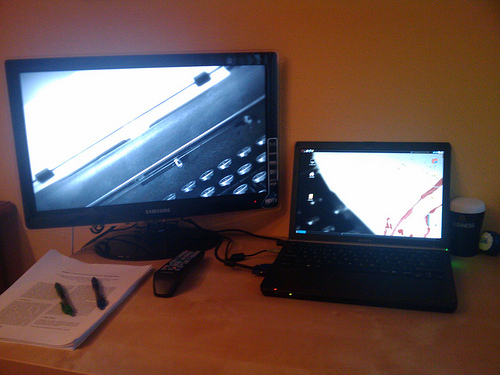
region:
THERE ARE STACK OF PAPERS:
[0, 245, 153, 356]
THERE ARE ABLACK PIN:
[51, 278, 76, 318]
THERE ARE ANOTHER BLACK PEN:
[89, 272, 109, 314]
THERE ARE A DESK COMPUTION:
[0, 49, 279, 266]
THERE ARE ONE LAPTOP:
[258, 140, 461, 315]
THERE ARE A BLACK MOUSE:
[152, 245, 215, 295]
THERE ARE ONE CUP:
[446, 195, 484, 260]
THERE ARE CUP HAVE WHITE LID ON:
[448, 195, 486, 217]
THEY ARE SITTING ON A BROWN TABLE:
[0, 45, 497, 372]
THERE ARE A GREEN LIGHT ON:
[285, 287, 296, 297]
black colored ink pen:
[87, 274, 110, 311]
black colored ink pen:
[51, 278, 78, 320]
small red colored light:
[271, 285, 278, 290]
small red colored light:
[251, 198, 256, 203]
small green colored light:
[286, 291, 296, 296]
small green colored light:
[441, 246, 448, 250]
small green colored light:
[448, 258, 463, 268]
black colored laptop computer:
[262, 138, 462, 315]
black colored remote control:
[146, 239, 206, 299]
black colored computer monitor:
[6, 51, 288, 266]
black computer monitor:
[0, 50, 292, 267]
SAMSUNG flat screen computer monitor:
[1, 44, 287, 261]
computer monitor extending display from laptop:
[4, 55, 287, 264]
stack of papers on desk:
[0, 244, 138, 355]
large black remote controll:
[145, 245, 207, 312]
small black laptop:
[255, 125, 470, 316]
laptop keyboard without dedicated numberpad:
[268, 232, 467, 284]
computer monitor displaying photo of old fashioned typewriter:
[4, 56, 281, 219]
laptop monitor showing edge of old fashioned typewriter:
[280, 138, 460, 250]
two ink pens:
[44, 273, 119, 324]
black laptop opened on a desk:
[258, 137, 457, 315]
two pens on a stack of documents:
[49, 275, 111, 317]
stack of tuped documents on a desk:
[1, 246, 150, 351]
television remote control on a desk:
[150, 247, 205, 297]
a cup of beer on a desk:
[451, 193, 483, 258]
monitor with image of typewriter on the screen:
[8, 93, 285, 261]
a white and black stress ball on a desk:
[481, 230, 498, 250]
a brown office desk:
[8, 225, 496, 365]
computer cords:
[218, 222, 280, 277]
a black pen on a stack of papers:
[51, 277, 78, 318]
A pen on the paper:
[49, 278, 81, 323]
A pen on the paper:
[91, 271, 116, 313]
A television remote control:
[156, 243, 210, 300]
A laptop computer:
[259, 125, 474, 321]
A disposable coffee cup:
[444, 188, 488, 256]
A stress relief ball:
[476, 225, 498, 250]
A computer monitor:
[2, 45, 284, 228]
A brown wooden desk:
[133, 314, 475, 374]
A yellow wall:
[294, 14, 493, 125]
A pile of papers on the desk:
[1, 248, 149, 363]